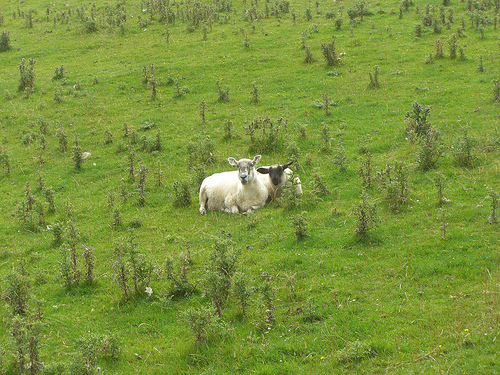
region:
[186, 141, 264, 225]
white cow sitting in field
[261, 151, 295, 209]
white cow sitting in field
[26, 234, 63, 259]
long green and yellow grass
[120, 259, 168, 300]
long green and yellow grass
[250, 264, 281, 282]
long green and yellow grass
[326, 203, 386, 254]
long green and yellow grass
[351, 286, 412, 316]
long green and yellow grass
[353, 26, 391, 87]
long green and yellow grass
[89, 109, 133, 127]
long green and yellow grass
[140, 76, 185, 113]
long green and yellow grass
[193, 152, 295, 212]
The sheep are lying down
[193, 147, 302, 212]
There are two sheep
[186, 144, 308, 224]
The sheep are on the grass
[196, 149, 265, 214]
The sheep is white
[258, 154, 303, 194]
The sheep has a black face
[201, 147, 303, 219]
The sheep are lying next to each other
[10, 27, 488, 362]
The sheep are on a grassy hill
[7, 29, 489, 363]
The grass is green with weeds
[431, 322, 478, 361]
Yellow flowers in grass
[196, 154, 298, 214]
The sheep are looking at the camera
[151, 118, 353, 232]
the sheep are resting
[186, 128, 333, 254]
two white sheep are resting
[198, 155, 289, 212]
Sheep in the field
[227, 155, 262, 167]
The ears of the sheep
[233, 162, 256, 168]
The eyes of the sheep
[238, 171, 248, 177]
The nose of the sheep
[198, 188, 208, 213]
The back legs of the sheep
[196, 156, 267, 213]
A white sheep in the grass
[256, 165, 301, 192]
A black sheep in the grass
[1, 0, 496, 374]
Grass below the sheep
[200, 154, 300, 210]
The sheep are sitting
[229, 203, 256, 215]
The front legs below the white sheep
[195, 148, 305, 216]
white cows lying on green grass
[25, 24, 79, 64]
long green and yellow grass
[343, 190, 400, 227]
long green and yellow grass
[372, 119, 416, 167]
long green and yellow grass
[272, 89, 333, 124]
long green and yellow grass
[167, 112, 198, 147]
long green and yellow grass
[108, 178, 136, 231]
long green and yellow grass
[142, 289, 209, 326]
long green and yellow grass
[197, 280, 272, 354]
long green and yellow grass